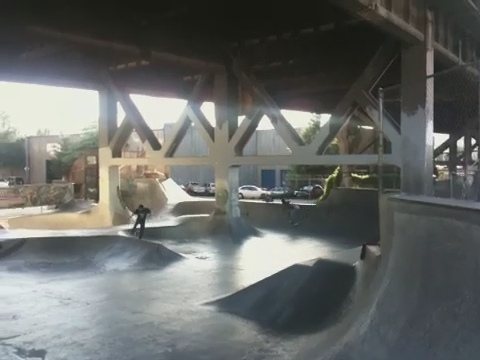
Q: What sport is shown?
A: Skateboarding.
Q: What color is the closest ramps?
A: Grey.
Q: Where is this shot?
A: Skate park.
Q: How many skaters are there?
A: 2.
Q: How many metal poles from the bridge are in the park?
A: 3.